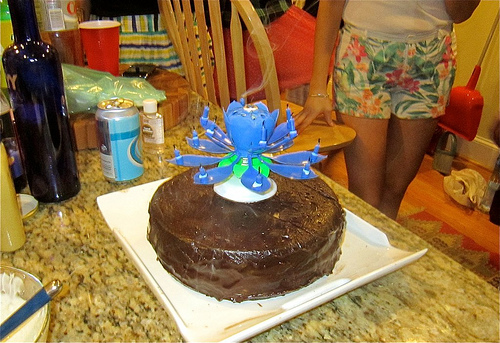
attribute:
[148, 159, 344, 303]
cake — chocolate, decorated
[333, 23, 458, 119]
shorts — floral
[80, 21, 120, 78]
cup — red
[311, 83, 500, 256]
floor — hardwood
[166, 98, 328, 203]
topper — fancy, blue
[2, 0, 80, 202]
container — dark blue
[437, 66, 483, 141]
dustpan — red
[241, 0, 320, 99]
smoke — curling